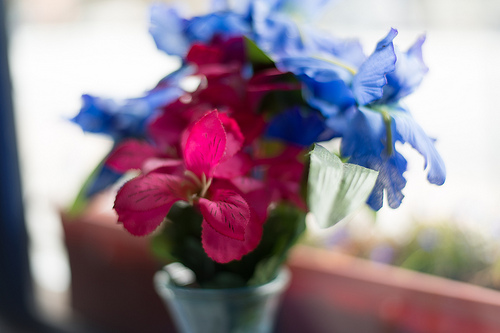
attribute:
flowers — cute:
[58, 3, 461, 274]